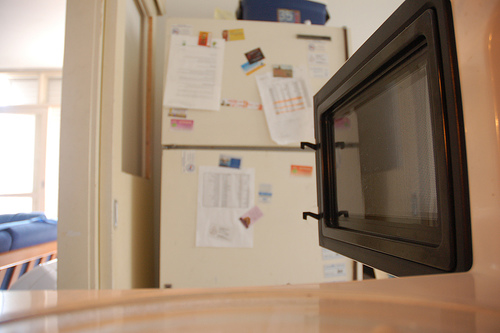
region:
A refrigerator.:
[160, 15, 375, 295]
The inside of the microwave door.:
[300, 0, 465, 280]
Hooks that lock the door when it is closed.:
[286, 130, 326, 230]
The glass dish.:
[0, 270, 490, 325]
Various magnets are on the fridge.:
[185, 25, 310, 245]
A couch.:
[0, 200, 55, 280]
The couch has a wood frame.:
[0, 240, 52, 290]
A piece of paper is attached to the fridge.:
[190, 160, 260, 255]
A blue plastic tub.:
[235, 0, 327, 27]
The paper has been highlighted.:
[256, 75, 316, 150]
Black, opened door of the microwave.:
[296, 55, 479, 278]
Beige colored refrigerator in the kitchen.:
[161, 10, 362, 285]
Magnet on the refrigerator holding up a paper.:
[211, 152, 246, 170]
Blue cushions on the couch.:
[0, 206, 57, 246]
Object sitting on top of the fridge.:
[232, 0, 336, 26]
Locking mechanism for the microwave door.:
[298, 207, 324, 222]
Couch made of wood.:
[1, 241, 58, 283]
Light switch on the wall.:
[105, 192, 125, 237]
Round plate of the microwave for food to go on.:
[15, 281, 480, 331]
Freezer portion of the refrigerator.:
[161, 13, 362, 146]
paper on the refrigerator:
[160, 121, 264, 261]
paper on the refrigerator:
[180, 158, 238, 252]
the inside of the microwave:
[6, 268, 499, 331]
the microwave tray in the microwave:
[0, 285, 497, 330]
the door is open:
[309, 0, 466, 281]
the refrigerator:
[157, 10, 379, 284]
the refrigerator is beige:
[152, 10, 386, 288]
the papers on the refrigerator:
[166, 25, 308, 257]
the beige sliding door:
[103, 0, 159, 286]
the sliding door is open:
[106, 1, 153, 288]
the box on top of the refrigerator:
[227, 5, 338, 32]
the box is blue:
[232, 0, 342, 34]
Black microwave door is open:
[283, 5, 490, 284]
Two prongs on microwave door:
[286, 133, 337, 240]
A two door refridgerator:
[140, 6, 388, 296]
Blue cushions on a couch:
[4, 203, 61, 271]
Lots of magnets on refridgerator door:
[184, 23, 322, 238]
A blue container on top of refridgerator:
[236, 3, 333, 31]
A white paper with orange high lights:
[254, 71, 328, 144]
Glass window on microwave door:
[315, 61, 451, 236]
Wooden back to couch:
[1, 236, 61, 294]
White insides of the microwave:
[1, 2, 498, 330]